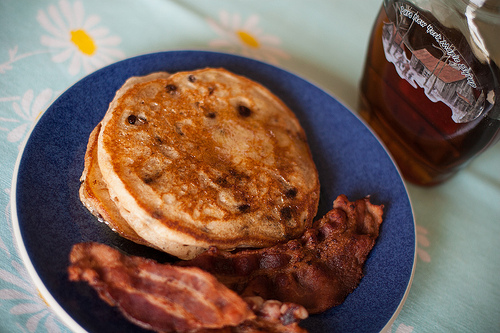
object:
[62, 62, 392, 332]
breakfast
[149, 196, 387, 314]
slices of bacon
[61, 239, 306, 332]
slice of bacon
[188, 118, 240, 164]
yellow center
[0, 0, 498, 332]
tablecloth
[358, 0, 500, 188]
maple syrup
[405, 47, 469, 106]
cabin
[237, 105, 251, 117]
chocolate chip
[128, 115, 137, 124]
black dot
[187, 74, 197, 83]
blueberries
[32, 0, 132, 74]
daisy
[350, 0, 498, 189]
bottle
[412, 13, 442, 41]
new york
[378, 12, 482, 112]
illustration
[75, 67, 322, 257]
pancake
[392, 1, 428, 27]
words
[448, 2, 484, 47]
reflection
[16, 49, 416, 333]
blue plate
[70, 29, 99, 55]
yellow center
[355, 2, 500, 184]
syrup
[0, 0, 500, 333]
table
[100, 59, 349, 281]
pancakes